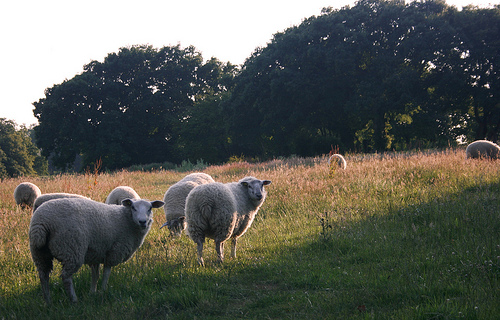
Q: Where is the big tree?
A: In the field.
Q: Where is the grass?
A: In the field.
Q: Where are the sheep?
A: In the field.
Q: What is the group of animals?
A: Sheep.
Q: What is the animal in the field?
A: Sheep.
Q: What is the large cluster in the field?
A: Trees.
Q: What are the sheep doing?
A: Grazing.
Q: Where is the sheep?
A: In the grass.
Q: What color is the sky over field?
A: Gray.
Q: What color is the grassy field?
A: Green.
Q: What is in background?
A: Row green trees.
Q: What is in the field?
A: Large tree.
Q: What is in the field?
A: Family of sheep.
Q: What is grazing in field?
A: The sheep.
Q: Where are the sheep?
A: In field of grass.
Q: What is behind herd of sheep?
A: The trees.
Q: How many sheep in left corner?
A: Five.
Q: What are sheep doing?
A: Grazing.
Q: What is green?
A: Grass.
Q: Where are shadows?
A: On the grass.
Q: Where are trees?
A: In the distance.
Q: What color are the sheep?
A: White.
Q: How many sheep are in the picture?
A: 8.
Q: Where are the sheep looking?
A: At the camera.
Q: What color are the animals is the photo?
A: White.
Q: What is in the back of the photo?
A: Trees.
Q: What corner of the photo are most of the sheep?
A: Bottom left.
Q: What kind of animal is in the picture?
A: Sheep.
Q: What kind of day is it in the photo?
A: Clear.